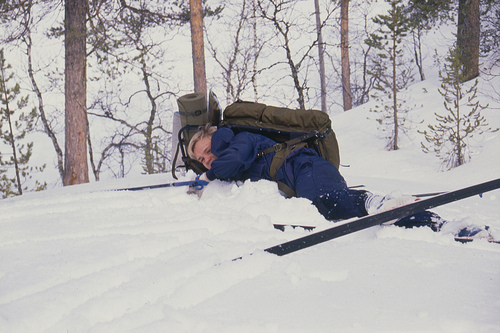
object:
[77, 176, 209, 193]
pole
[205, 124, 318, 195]
jacket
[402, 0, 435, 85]
trees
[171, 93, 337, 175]
backpack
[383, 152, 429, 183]
ground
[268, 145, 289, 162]
straps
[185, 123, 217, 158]
hair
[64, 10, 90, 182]
trunk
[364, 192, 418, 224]
ski boots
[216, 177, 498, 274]
metal ski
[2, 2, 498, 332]
snow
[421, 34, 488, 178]
tree saplings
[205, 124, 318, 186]
jacket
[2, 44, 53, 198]
tree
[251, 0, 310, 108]
tree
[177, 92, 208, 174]
bedroll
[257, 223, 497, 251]
ski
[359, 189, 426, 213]
foot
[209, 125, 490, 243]
suit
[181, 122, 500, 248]
skier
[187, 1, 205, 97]
tree trunks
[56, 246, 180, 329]
tracks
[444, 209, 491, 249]
boot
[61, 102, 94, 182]
trunk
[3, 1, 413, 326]
mountainside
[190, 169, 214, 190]
wrist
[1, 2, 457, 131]
background